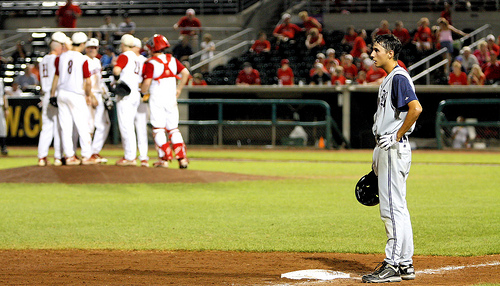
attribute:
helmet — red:
[141, 29, 173, 61]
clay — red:
[4, 245, 499, 283]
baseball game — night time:
[6, 3, 436, 284]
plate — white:
[280, 263, 357, 283]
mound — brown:
[0, 159, 292, 187]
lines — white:
[351, 257, 498, 277]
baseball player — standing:
[351, 33, 481, 254]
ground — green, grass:
[367, 122, 423, 166]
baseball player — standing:
[47, 28, 102, 168]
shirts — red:
[344, 58, 435, 137]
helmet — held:
[344, 160, 386, 226]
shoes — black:
[360, 258, 400, 284]